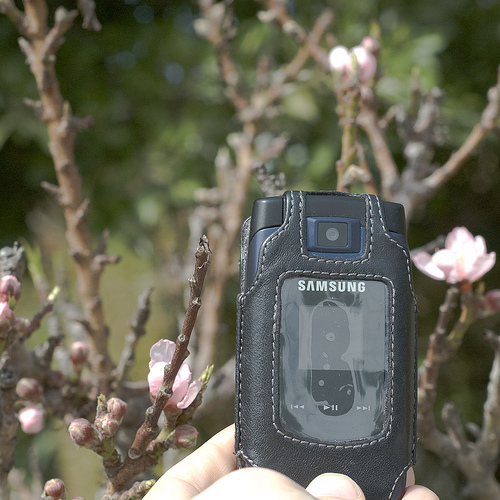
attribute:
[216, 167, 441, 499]
phone — black, blue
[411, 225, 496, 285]
flower — pink 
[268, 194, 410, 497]
case — black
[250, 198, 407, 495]
phone — blue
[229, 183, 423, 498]
case — plastic, black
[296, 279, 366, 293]
print — SAMSUNG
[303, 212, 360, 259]
camera — built-in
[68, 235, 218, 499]
branch — one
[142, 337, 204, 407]
pink flower — bud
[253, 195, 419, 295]
cellphone — blue, black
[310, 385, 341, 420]
sign — play, pause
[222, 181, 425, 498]
phone — black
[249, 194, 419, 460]
cellphone — blue, black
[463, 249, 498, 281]
petal — pink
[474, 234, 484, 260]
petal — pink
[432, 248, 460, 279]
petal — pink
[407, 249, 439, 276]
petal — pink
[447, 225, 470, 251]
petal — pink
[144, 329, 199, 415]
petal — pink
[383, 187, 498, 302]
flower bud — pink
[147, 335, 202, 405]
flower — pink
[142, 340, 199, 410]
flower — pink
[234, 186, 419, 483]
phone — black 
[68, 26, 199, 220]
foliage — green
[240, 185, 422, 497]
cell phone — SAMSUNG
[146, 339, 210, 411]
petal — pink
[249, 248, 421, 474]
thread — white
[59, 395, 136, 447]
buds — flower, unopened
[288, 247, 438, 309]
samsung — white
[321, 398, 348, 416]
button — play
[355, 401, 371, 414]
sign — forward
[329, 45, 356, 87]
petal — pink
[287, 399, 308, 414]
sign — rewind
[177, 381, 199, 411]
petal — pink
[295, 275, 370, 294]
name — samsung